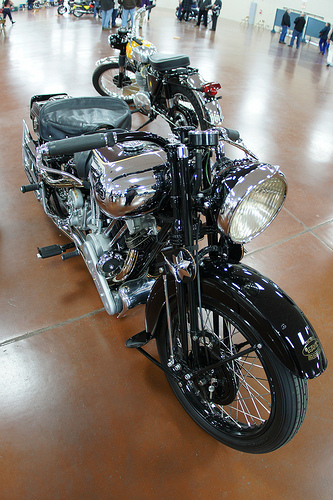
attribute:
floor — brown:
[0, 7, 333, 498]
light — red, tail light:
[200, 79, 220, 97]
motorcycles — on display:
[92, 5, 224, 138]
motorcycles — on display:
[19, 93, 327, 453]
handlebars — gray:
[77, 111, 296, 191]